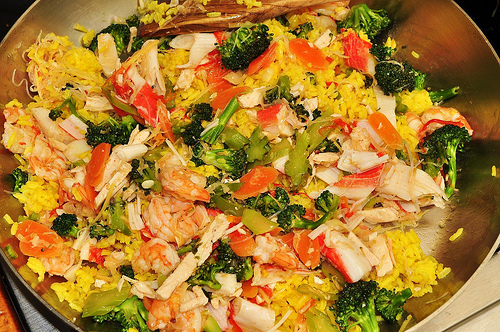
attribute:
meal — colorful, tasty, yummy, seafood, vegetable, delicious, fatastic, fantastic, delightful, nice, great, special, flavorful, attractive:
[5, 0, 473, 332]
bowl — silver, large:
[2, 0, 500, 331]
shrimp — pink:
[149, 192, 203, 241]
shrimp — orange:
[161, 165, 214, 204]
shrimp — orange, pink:
[133, 238, 180, 274]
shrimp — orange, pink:
[149, 287, 199, 331]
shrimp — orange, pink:
[423, 103, 472, 138]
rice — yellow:
[256, 20, 374, 117]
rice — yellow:
[370, 226, 438, 294]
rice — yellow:
[74, 24, 95, 47]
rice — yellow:
[15, 176, 60, 213]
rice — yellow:
[50, 264, 94, 312]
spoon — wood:
[138, 0, 346, 36]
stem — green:
[356, 312, 377, 331]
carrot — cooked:
[368, 111, 404, 148]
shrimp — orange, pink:
[27, 146, 68, 180]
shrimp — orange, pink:
[404, 109, 426, 138]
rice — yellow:
[27, 31, 105, 97]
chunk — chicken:
[159, 251, 198, 299]